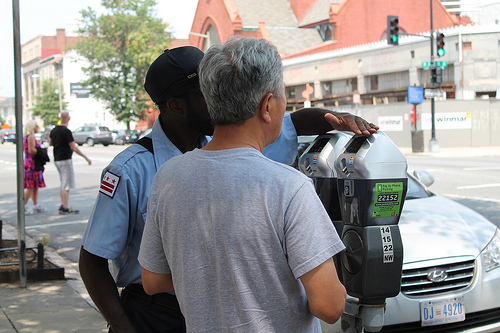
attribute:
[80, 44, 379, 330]
man — helping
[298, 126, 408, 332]
meter — grey, black, silver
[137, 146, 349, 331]
shirt — gray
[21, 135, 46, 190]
dress — multi-color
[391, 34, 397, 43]
light — green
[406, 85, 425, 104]
sign — blue, white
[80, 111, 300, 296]
shirt — blue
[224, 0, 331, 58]
roof — orange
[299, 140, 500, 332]
car — white, parked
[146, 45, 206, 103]
hat — black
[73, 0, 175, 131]
tree — green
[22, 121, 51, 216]
woman — blonde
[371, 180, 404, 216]
sticker — green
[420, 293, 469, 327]
license plate — blue, white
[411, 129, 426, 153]
pillar — stone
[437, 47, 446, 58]
light — green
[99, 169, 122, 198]
patch — white, black white, red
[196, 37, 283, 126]
hair — gray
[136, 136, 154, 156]
strap — black